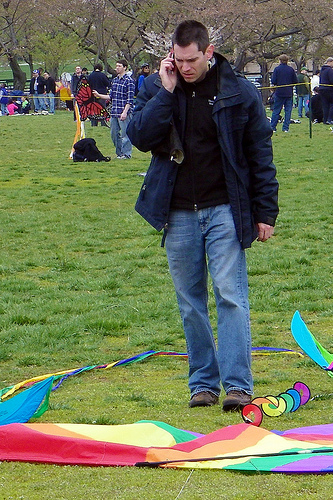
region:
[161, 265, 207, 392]
leg of a person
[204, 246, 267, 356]
leg of a person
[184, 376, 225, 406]
feet of a person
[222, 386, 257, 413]
feet of a person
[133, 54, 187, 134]
arm of a person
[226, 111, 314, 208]
arm of a person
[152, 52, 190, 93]
hand of a person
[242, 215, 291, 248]
hand of a person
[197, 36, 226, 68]
ear of a person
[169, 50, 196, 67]
eye of a person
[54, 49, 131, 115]
a peson holding a kite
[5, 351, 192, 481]
a kite laying on the ground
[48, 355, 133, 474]
a ground under a kite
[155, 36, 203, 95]
a guy talking on a cell phone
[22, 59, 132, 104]
people gathering on a field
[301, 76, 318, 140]
a post supporting rope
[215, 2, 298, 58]
trees growing in a park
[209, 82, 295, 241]
a guy wearing a blue jacket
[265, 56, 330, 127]
people standing in a park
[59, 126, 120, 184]
a bag sitting on the ground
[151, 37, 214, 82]
a person holding his cellular phone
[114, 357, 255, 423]
a person standing on the ground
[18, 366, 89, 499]
a kite laying on the ground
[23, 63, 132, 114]
people gathering in a park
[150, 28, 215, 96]
a person talking on cellular phone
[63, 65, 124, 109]
a person holding a kite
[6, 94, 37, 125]
kids sitting on the ground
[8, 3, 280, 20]
trees surrounding a park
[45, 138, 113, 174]
a bag sitting on the ground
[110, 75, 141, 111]
a person wearing a plaid shirt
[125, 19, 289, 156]
a man talking on a cellphone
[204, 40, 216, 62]
the ear of a man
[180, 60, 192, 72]
the nose of a man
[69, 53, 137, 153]
a man holding a red and black butterfly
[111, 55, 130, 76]
the head of a man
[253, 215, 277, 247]
the hand of a man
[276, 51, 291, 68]
the head of a person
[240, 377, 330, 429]
the tail of a kite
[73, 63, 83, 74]
the head of a man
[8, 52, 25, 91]
a trunk of a tree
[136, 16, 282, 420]
This is a person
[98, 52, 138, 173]
This is a person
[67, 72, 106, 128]
This is a person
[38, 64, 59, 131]
This is a person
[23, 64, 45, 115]
This is a person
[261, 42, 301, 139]
This is a person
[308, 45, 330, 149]
This is a person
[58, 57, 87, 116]
This is a person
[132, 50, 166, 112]
This is a person